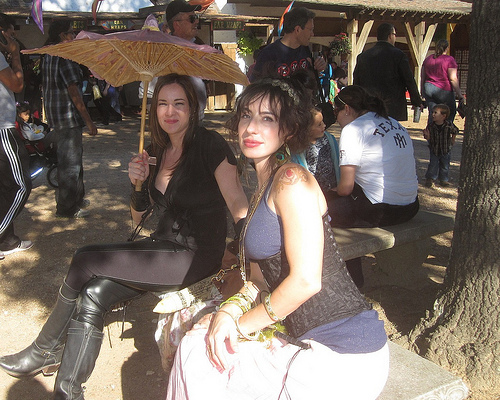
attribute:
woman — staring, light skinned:
[165, 80, 388, 400]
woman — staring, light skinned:
[1, 73, 248, 399]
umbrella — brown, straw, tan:
[20, 13, 250, 192]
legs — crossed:
[1, 235, 192, 399]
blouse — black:
[134, 124, 239, 254]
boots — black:
[0, 283, 104, 399]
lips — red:
[241, 135, 263, 150]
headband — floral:
[243, 79, 300, 106]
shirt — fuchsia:
[421, 53, 458, 92]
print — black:
[372, 114, 406, 139]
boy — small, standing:
[421, 104, 459, 187]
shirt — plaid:
[427, 121, 460, 156]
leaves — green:
[236, 28, 263, 57]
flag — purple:
[30, 0, 47, 36]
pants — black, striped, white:
[1, 127, 31, 241]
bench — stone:
[373, 337, 470, 399]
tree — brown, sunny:
[390, 1, 499, 399]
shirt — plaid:
[38, 47, 84, 131]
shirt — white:
[337, 109, 418, 205]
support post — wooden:
[346, 14, 373, 89]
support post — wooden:
[399, 16, 438, 97]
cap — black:
[165, 0, 203, 17]